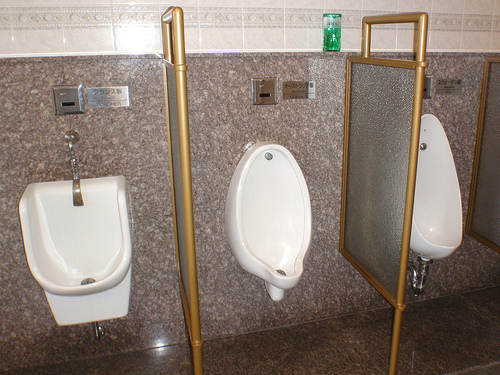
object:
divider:
[162, 6, 204, 374]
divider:
[337, 11, 431, 373]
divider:
[464, 54, 500, 258]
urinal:
[408, 113, 466, 268]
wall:
[2, 2, 499, 372]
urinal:
[222, 139, 316, 305]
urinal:
[15, 172, 138, 332]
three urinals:
[17, 110, 468, 327]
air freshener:
[320, 11, 344, 51]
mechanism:
[52, 84, 87, 115]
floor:
[2, 282, 499, 374]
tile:
[1, 1, 498, 54]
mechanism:
[252, 76, 277, 106]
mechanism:
[421, 73, 431, 98]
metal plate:
[83, 85, 128, 108]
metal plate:
[281, 79, 310, 98]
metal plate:
[432, 76, 461, 94]